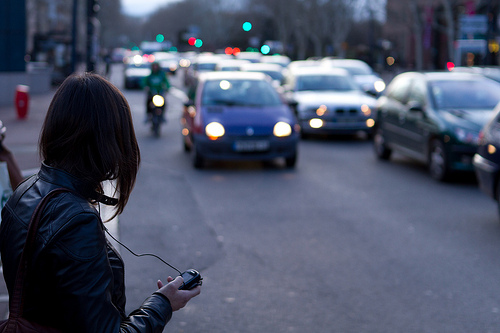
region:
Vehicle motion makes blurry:
[139, 33, 499, 183]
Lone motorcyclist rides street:
[136, 58, 176, 140]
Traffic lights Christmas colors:
[154, 19, 291, 59]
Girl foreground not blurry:
[7, 83, 207, 331]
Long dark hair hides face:
[32, 64, 143, 204]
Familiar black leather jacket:
[13, 198, 174, 332]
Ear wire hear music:
[107, 223, 214, 313]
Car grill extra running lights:
[311, 99, 380, 135]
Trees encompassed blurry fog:
[84, 0, 238, 34]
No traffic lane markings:
[224, 135, 499, 318]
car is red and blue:
[170, 56, 315, 225]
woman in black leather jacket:
[8, 47, 210, 329]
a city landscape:
[22, 5, 488, 325]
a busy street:
[40, 6, 462, 319]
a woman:
[7, 68, 202, 324]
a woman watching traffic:
[19, 62, 240, 331]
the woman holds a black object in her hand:
[3, 53, 223, 331]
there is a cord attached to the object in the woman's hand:
[18, 66, 268, 326]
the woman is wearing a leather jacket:
[6, 68, 209, 329]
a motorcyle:
[127, 52, 182, 174]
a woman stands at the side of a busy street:
[14, 62, 294, 331]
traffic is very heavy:
[66, 7, 495, 215]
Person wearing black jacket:
[0, 66, 252, 331]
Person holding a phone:
[1, 58, 233, 331]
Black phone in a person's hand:
[150, 257, 215, 311]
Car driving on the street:
[163, 58, 318, 175]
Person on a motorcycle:
[136, 53, 180, 151]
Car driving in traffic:
[273, 50, 390, 149]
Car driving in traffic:
[360, 64, 498, 184]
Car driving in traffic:
[118, 51, 154, 96]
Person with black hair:
[0, 44, 235, 324]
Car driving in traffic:
[318, 44, 406, 103]